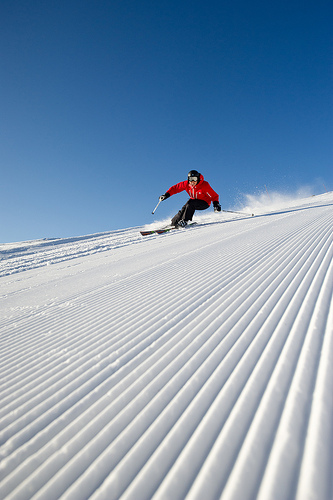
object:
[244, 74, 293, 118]
clouds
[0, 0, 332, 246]
blue sky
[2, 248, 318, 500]
lines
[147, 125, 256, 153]
clouds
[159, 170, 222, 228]
skier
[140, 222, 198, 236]
skis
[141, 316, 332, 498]
snow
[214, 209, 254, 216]
pole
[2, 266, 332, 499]
slope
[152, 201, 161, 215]
pole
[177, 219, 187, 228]
shoes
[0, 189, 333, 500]
hill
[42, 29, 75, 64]
clouds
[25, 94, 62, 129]
clouds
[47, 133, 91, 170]
clouds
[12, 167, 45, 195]
clouds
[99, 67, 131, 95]
clouds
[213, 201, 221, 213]
left hand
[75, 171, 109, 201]
clouds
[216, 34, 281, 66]
clouds